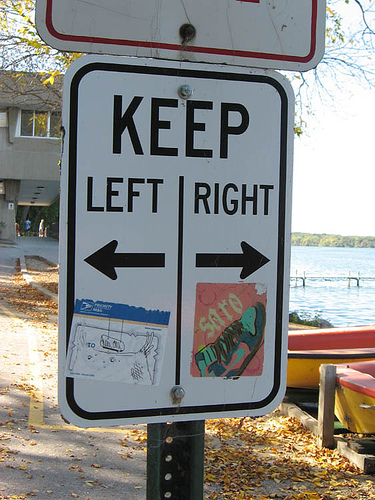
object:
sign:
[83, 90, 273, 281]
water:
[289, 242, 373, 328]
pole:
[145, 419, 205, 500]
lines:
[27, 423, 148, 436]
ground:
[0, 275, 375, 500]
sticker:
[189, 281, 267, 380]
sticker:
[64, 299, 170, 388]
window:
[17, 107, 61, 139]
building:
[0, 68, 63, 245]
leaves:
[202, 411, 375, 500]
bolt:
[171, 384, 185, 400]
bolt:
[177, 83, 192, 100]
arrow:
[195, 241, 271, 279]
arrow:
[83, 240, 165, 281]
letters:
[86, 95, 274, 216]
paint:
[286, 352, 374, 387]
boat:
[285, 325, 375, 391]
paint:
[288, 327, 374, 357]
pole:
[317, 362, 337, 448]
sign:
[32, 3, 328, 73]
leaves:
[0, 254, 61, 331]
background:
[10, 8, 373, 283]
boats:
[318, 360, 375, 433]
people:
[24, 217, 32, 237]